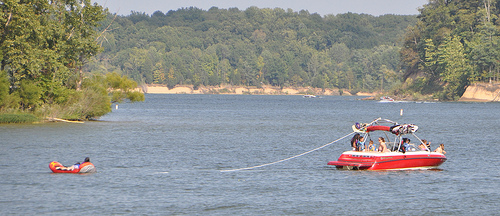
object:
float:
[49, 157, 94, 174]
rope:
[217, 117, 383, 173]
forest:
[1, 0, 498, 128]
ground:
[412, 122, 452, 169]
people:
[348, 132, 445, 153]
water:
[0, 91, 500, 213]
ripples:
[196, 198, 500, 216]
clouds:
[84, 0, 443, 16]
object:
[55, 162, 81, 173]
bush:
[0, 27, 147, 122]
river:
[166, 96, 273, 133]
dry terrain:
[80, 85, 383, 96]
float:
[329, 149, 444, 172]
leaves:
[0, 0, 98, 99]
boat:
[328, 117, 449, 168]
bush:
[446, 62, 500, 94]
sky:
[55, 1, 430, 19]